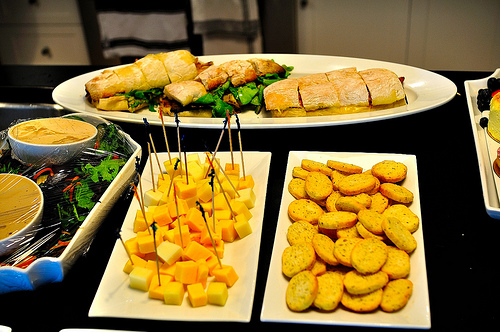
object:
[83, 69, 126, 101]
bread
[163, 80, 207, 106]
bread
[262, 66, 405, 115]
bread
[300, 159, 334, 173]
bread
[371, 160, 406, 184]
bread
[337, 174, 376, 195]
bread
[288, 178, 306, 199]
bread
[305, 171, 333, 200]
bread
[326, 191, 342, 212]
bread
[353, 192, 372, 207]
bread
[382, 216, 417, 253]
bread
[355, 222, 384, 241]
bread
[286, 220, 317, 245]
bread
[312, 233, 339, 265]
bread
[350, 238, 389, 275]
bread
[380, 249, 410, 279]
bread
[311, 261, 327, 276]
bread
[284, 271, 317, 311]
bread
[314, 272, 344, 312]
bread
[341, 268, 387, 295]
bread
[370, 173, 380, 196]
bread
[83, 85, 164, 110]
sandwich segment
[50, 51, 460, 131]
plate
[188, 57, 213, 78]
sandwich segment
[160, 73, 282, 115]
sandwich segment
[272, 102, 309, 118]
sandwich segment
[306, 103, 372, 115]
sandwich segment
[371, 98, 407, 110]
sandwich segment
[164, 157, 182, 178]
cheese cube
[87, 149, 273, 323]
plate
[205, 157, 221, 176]
cheese cube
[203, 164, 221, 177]
cheese cube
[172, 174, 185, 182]
cheese cube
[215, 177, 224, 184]
cheese cube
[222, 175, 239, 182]
cheese cube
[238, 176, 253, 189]
cheese cube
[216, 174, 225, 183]
cheese cube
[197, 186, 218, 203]
cheese cube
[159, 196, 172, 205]
cheese cube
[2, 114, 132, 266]
salad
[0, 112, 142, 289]
plate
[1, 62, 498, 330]
table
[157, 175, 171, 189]
cheese cube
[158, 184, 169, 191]
cheese cube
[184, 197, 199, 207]
cheese cube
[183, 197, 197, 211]
cheese cube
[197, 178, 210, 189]
cheese cube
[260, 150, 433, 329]
plate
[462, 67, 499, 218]
plate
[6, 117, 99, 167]
bowl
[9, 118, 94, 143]
salad dressing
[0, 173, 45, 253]
bowl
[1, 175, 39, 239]
salad dressing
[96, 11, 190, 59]
towel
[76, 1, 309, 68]
stove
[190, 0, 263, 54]
towel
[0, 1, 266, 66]
cabinet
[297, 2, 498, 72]
cabinet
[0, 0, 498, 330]
kitchen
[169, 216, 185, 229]
cheese cube